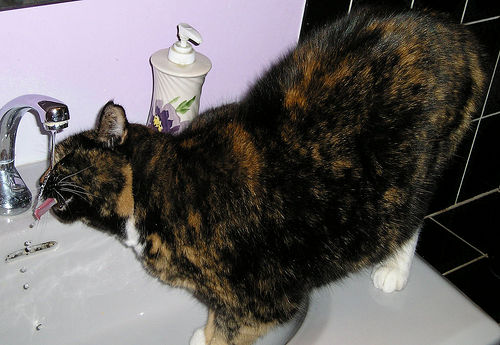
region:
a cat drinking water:
[11, 93, 157, 258]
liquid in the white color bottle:
[153, 7, 213, 158]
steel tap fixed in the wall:
[3, 75, 75, 249]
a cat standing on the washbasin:
[46, 44, 478, 343]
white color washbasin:
[11, 230, 473, 343]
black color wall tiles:
[323, 11, 495, 246]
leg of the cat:
[359, 228, 419, 305]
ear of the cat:
[91, 93, 143, 143]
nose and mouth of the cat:
[26, 167, 90, 222]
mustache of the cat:
[58, 168, 105, 208]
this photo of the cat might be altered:
[10, 15, 498, 260]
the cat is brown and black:
[30, 75, 465, 315]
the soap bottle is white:
[125, 15, 220, 145]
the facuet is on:
[0, 90, 65, 220]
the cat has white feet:
[360, 215, 415, 310]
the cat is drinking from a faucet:
[25, 95, 200, 270]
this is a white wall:
[30, 15, 155, 110]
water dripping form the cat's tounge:
[0, 195, 56, 331]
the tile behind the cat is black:
[412, 0, 497, 275]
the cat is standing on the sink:
[31, 54, 404, 344]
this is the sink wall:
[81, 21, 121, 48]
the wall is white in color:
[213, 19, 263, 58]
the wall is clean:
[229, 11, 263, 44]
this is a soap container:
[158, 46, 193, 128]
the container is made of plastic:
[174, 66, 194, 82]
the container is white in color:
[177, 65, 194, 80]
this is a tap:
[5, 90, 66, 150]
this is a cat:
[52, 20, 441, 331]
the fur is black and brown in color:
[381, 25, 441, 85]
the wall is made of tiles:
[466, 176, 486, 216]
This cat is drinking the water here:
[42, 143, 75, 208]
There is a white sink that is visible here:
[383, 302, 412, 337]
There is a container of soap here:
[165, 23, 202, 69]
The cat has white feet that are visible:
[388, 244, 417, 315]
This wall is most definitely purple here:
[69, 16, 97, 67]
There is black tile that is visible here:
[466, 157, 486, 225]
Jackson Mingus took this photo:
[81, 48, 351, 296]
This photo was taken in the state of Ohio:
[87, 19, 397, 334]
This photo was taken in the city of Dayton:
[66, 22, 373, 329]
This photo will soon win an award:
[64, 18, 339, 342]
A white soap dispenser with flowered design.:
[124, 13, 226, 185]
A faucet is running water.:
[0, 78, 72, 225]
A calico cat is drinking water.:
[9, 3, 492, 343]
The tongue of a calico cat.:
[21, 185, 73, 228]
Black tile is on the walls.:
[397, 127, 499, 312]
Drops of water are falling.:
[9, 212, 61, 337]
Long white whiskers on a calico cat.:
[49, 157, 114, 204]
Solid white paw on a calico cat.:
[357, 195, 452, 307]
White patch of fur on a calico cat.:
[93, 211, 165, 277]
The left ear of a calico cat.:
[83, 95, 138, 158]